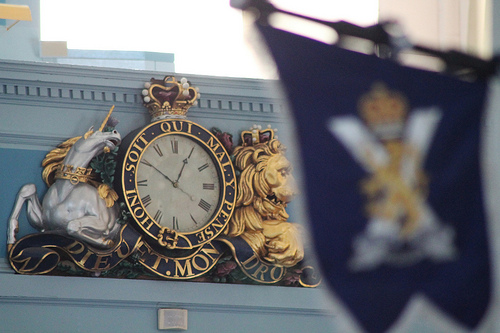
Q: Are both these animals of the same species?
A: No, they are lions and horses.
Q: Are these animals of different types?
A: Yes, they are lions and horses.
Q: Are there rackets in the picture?
A: No, there are no rackets.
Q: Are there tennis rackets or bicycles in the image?
A: No, there are no tennis rackets or bicycles.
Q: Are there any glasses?
A: No, there are no glasses.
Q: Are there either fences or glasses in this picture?
A: No, there are no glasses or fences.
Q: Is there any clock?
A: Yes, there is a clock.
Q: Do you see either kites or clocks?
A: Yes, there is a clock.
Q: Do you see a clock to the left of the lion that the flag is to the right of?
A: Yes, there is a clock to the left of the lion.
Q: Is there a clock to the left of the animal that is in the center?
A: Yes, there is a clock to the left of the lion.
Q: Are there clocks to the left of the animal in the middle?
A: Yes, there is a clock to the left of the lion.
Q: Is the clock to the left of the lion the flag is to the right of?
A: Yes, the clock is to the left of the lion.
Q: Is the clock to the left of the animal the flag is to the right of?
A: Yes, the clock is to the left of the lion.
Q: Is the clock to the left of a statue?
A: No, the clock is to the left of the lion.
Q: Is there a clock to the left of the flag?
A: Yes, there is a clock to the left of the flag.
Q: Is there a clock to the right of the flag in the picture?
A: No, the clock is to the left of the flag.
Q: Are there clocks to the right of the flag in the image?
A: No, the clock is to the left of the flag.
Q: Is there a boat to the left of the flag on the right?
A: No, there is a clock to the left of the flag.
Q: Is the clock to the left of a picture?
A: No, the clock is to the left of the flag.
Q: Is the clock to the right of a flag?
A: No, the clock is to the left of a flag.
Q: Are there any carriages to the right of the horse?
A: No, there is a clock to the right of the horse.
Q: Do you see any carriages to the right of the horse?
A: No, there is a clock to the right of the horse.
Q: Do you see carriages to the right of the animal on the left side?
A: No, there is a clock to the right of the horse.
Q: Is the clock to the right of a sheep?
A: No, the clock is to the right of the horse.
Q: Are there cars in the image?
A: No, there are no cars.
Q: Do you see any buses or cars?
A: No, there are no cars or buses.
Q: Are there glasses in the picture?
A: No, there are no glasses.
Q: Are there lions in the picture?
A: Yes, there is a lion.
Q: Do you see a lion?
A: Yes, there is a lion.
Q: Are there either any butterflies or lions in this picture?
A: Yes, there is a lion.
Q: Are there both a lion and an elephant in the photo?
A: No, there is a lion but no elephants.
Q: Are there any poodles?
A: No, there are no poodles.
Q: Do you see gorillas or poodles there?
A: No, there are no poodles or gorillas.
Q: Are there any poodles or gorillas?
A: No, there are no poodles or gorillas.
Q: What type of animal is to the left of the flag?
A: The animal is a lion.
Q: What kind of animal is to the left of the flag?
A: The animal is a lion.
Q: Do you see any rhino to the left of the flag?
A: No, there is a lion to the left of the flag.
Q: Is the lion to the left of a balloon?
A: No, the lion is to the left of the flag.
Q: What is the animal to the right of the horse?
A: The animal is a lion.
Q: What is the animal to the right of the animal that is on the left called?
A: The animal is a lion.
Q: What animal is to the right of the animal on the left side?
A: The animal is a lion.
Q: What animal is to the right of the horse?
A: The animal is a lion.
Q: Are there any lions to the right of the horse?
A: Yes, there is a lion to the right of the horse.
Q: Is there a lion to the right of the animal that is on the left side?
A: Yes, there is a lion to the right of the horse.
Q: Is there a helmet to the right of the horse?
A: No, there is a lion to the right of the horse.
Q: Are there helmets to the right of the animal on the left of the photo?
A: No, there is a lion to the right of the horse.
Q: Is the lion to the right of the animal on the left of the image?
A: Yes, the lion is to the right of the horse.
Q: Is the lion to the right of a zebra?
A: No, the lion is to the right of the horse.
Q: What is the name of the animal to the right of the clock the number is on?
A: The animal is a lion.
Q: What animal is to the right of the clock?
A: The animal is a lion.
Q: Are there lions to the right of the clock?
A: Yes, there is a lion to the right of the clock.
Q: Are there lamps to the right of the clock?
A: No, there is a lion to the right of the clock.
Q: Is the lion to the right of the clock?
A: Yes, the lion is to the right of the clock.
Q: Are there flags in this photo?
A: Yes, there is a flag.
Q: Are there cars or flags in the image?
A: Yes, there is a flag.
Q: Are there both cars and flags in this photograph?
A: No, there is a flag but no cars.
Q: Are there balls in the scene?
A: No, there are no balls.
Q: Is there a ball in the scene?
A: No, there are no balls.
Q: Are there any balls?
A: No, there are no balls.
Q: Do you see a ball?
A: No, there are no balls.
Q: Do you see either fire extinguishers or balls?
A: No, there are no balls or fire extinguishers.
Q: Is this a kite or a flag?
A: This is a flag.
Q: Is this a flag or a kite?
A: This is a flag.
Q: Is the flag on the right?
A: Yes, the flag is on the right of the image.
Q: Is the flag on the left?
A: No, the flag is on the right of the image.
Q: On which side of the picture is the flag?
A: The flag is on the right of the image.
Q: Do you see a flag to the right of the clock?
A: Yes, there is a flag to the right of the clock.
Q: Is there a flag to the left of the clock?
A: No, the flag is to the right of the clock.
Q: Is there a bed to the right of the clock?
A: No, there is a flag to the right of the clock.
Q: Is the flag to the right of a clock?
A: Yes, the flag is to the right of a clock.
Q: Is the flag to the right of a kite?
A: No, the flag is to the right of a clock.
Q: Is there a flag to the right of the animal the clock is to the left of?
A: Yes, there is a flag to the right of the lion.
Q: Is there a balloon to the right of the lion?
A: No, there is a flag to the right of the lion.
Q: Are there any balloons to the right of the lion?
A: No, there is a flag to the right of the lion.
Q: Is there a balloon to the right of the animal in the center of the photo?
A: No, there is a flag to the right of the lion.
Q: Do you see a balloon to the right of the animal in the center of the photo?
A: No, there is a flag to the right of the lion.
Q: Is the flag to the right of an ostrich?
A: No, the flag is to the right of the lion.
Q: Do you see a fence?
A: No, there are no fences.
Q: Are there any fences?
A: No, there are no fences.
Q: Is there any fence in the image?
A: No, there are no fences.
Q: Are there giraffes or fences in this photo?
A: No, there are no fences or giraffes.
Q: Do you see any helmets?
A: No, there are no helmets.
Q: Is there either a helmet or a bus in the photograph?
A: No, there are no helmets or buses.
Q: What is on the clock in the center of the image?
A: The number is on the clock.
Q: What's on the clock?
A: The number is on the clock.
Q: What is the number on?
A: The number is on the clock.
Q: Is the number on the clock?
A: Yes, the number is on the clock.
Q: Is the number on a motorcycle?
A: No, the number is on the clock.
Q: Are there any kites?
A: No, there are no kites.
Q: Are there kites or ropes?
A: No, there are no kites or ropes.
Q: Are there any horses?
A: Yes, there is a horse.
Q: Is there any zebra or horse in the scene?
A: Yes, there is a horse.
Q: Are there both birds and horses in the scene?
A: No, there is a horse but no birds.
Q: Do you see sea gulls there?
A: No, there are no sea gulls.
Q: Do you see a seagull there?
A: No, there are no seagulls.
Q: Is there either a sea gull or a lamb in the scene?
A: No, there are no seagulls or lambs.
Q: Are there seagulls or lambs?
A: No, there are no seagulls or lambs.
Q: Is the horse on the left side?
A: Yes, the horse is on the left of the image.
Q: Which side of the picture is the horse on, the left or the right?
A: The horse is on the left of the image.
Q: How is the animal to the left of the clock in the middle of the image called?
A: The animal is a horse.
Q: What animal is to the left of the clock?
A: The animal is a horse.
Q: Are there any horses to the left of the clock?
A: Yes, there is a horse to the left of the clock.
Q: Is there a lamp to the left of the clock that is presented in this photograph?
A: No, there is a horse to the left of the clock.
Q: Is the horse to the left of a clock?
A: Yes, the horse is to the left of a clock.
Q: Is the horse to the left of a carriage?
A: No, the horse is to the left of a clock.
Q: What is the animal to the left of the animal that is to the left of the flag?
A: The animal is a horse.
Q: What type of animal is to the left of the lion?
A: The animal is a horse.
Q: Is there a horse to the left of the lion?
A: Yes, there is a horse to the left of the lion.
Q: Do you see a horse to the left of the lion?
A: Yes, there is a horse to the left of the lion.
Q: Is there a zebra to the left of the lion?
A: No, there is a horse to the left of the lion.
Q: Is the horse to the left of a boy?
A: No, the horse is to the left of the lion.